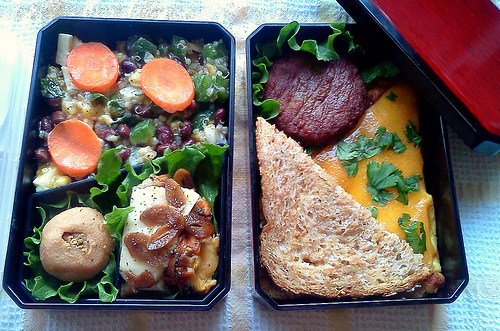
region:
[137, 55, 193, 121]
Round orange carrot slice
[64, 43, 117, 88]
Round orange carrot slice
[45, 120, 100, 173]
Round orange carrot slice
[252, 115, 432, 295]
Bread in blue container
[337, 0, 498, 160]
Top of blue container resting on blue container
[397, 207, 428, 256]
Parsley on top of cheese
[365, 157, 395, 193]
Parsley on top of cheese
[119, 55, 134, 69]
Bean next to carrot slice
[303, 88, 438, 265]
Melted cheese next to bread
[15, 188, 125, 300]
Green leaf underneath food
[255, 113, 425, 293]
Bread next to yellow cheese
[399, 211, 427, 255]
Parsley on yellow cheese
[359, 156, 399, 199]
Parsley on yellow cheese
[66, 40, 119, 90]
Round orange carrot slice next to bean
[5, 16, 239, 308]
Blue container next to blue container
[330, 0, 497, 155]
Wooden container top on blue container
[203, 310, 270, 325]
edge of white and yellow square tablecloth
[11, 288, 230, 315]
edge of blue food container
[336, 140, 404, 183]
green basil on food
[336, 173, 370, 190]
gooey yellow American cheese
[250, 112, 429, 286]
half slice of wheat bread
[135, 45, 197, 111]
round slice of orange carrot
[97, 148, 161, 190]
crisp green lettuce leaves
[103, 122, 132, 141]
shiny red kidney beans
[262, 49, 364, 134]
brown hamburger patty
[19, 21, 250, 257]
blue tray filled with lunch food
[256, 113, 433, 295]
slice of whole wheat bread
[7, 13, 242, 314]
black bento box next to bento box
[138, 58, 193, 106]
sliced orange carrot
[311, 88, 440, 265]
cheddar cheese next to bread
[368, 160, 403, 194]
green parsley on orange cheese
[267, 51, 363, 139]
round piece of meat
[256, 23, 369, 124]
lettuce leaf under meat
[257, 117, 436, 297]
bread next to meat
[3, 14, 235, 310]
bento box to the left of bento box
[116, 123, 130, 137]
bean next to carrot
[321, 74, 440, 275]
Yellow cheese on bread